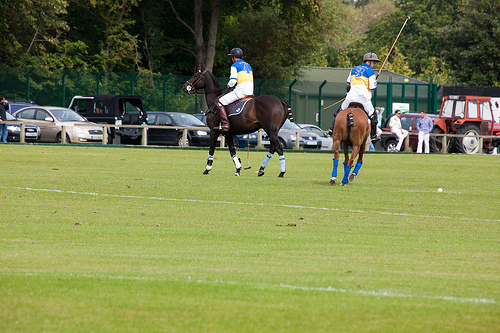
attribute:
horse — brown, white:
[188, 69, 294, 185]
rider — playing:
[220, 40, 254, 116]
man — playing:
[338, 51, 374, 112]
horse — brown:
[332, 104, 364, 193]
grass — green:
[42, 200, 67, 231]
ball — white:
[428, 184, 447, 202]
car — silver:
[21, 96, 104, 148]